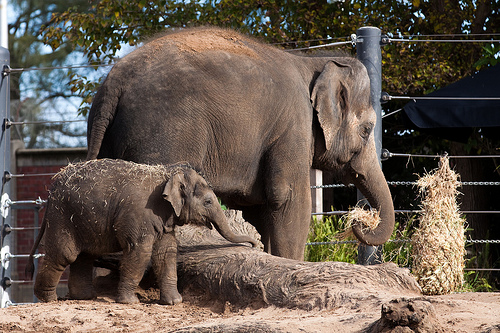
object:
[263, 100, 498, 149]
wall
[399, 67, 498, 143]
covering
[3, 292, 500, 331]
ground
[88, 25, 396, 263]
elephant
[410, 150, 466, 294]
basket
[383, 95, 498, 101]
wire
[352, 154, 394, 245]
trunk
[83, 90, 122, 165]
tail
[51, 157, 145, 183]
back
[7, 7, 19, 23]
sky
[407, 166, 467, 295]
tree trunk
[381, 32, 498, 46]
wires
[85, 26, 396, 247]
large elephant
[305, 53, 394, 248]
elephant eating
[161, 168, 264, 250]
head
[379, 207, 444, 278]
grass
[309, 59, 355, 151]
ear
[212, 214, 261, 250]
trunk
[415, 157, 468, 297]
straw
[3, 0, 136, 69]
branch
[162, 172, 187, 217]
ear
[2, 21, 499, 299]
fence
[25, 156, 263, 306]
elephant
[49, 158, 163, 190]
straw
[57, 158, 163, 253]
body